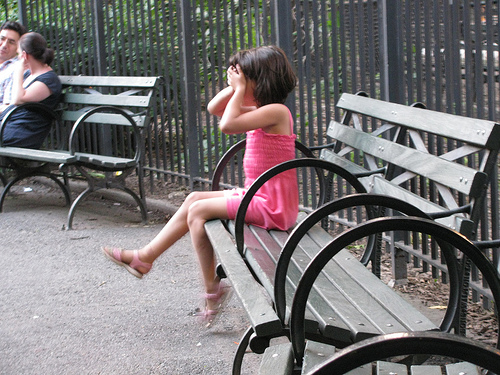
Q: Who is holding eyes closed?
A: A girl.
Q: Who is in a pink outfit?
A: A young girl.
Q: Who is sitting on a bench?
A: A young girl.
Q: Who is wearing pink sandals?
A: A young girl.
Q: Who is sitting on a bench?
A: Young girl.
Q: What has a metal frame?
A: A wood bench.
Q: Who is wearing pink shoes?
A: A young girl.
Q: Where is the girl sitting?
A: On bench.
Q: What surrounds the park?
A: Black fence.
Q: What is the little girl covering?
A: The eyes.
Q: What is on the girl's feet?
A: Sandals.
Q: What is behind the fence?
A: Trees.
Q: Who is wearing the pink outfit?
A: Little girl.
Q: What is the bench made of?
A: Wood and metal.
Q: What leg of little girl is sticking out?
A: Right leg.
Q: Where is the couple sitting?
A: On a bench.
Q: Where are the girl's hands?
A: On her face.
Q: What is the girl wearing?
A: A pink dress.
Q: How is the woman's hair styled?
A: It is tied back.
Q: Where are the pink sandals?
A: On the girl's feet.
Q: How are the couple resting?
A: They are sitting.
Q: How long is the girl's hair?
A: Shoulder length.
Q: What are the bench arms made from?
A: Metal.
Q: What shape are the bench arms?
A: Circular.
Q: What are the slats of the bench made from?
A: Wood.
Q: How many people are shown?
A: Three.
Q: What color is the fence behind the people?
A: Gray.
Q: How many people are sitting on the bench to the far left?
A: Two.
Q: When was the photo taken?
A: Daytime.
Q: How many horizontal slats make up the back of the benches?
A: Three.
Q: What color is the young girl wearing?
A: Pink.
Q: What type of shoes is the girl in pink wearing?
A: Sandals.